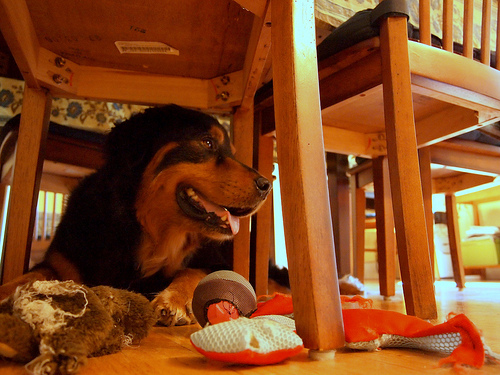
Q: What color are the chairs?
A: Brown.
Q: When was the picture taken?
A: Daytime.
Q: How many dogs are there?
A: One.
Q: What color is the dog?
A: Brown and black.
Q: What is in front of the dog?
A: Toys.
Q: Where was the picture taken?
A: Under a dining table.